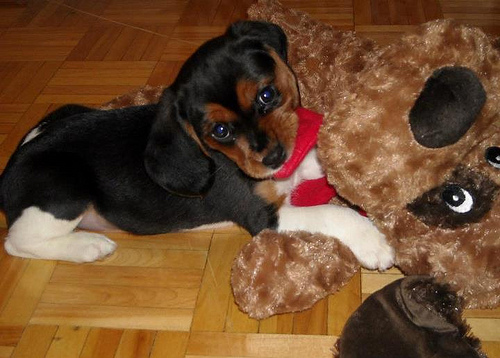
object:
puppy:
[0, 19, 395, 271]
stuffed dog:
[95, 1, 497, 358]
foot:
[1, 230, 117, 264]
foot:
[98, 85, 170, 112]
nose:
[261, 150, 284, 168]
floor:
[0, 1, 255, 173]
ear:
[328, 276, 486, 358]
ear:
[143, 85, 217, 199]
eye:
[256, 86, 278, 105]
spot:
[21, 123, 46, 146]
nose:
[407, 64, 485, 148]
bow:
[313, 107, 338, 202]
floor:
[0, 223, 498, 357]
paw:
[337, 211, 397, 272]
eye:
[441, 185, 472, 214]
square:
[63, 23, 176, 62]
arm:
[226, 228, 361, 322]